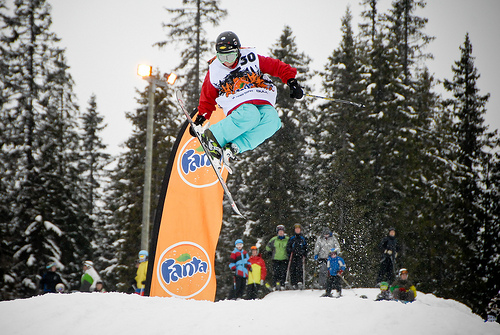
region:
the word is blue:
[164, 254, 207, 284]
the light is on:
[131, 56, 157, 81]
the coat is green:
[273, 237, 283, 255]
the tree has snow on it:
[32, 189, 67, 239]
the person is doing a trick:
[206, 40, 263, 183]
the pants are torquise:
[236, 115, 255, 133]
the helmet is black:
[209, 36, 250, 54]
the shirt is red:
[264, 57, 288, 73]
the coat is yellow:
[135, 260, 147, 282]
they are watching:
[226, 215, 357, 284]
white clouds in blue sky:
[62, 10, 111, 44]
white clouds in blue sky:
[89, 19, 144, 88]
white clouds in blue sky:
[232, 7, 288, 34]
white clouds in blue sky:
[446, 10, 487, 26]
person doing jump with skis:
[172, 31, 313, 187]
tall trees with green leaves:
[11, 20, 67, 180]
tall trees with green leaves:
[53, 90, 105, 235]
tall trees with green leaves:
[176, 7, 211, 48]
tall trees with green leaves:
[337, 30, 388, 210]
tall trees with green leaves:
[431, 38, 491, 239]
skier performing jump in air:
[176, 30, 363, 217]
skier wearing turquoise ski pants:
[205, 102, 283, 154]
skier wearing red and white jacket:
[196, 45, 297, 120]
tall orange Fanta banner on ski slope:
[146, 105, 229, 301]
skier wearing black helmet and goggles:
[215, 30, 241, 65]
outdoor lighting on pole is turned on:
[137, 63, 177, 293]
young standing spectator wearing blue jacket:
[323, 248, 348, 296]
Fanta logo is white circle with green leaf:
[157, 240, 212, 295]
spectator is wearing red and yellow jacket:
[244, 253, 267, 285]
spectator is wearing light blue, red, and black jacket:
[227, 246, 249, 275]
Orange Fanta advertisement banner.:
[154, 109, 227, 301]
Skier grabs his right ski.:
[168, 11, 365, 228]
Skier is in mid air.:
[176, 28, 353, 223]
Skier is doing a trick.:
[166, 23, 346, 213]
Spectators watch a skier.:
[225, 218, 417, 310]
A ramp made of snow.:
[2, 287, 477, 332]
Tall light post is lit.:
[128, 58, 174, 288]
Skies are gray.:
[13, 0, 498, 117]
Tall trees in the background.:
[5, 0, 491, 289]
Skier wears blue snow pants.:
[200, 93, 295, 152]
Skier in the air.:
[141, 27, 397, 242]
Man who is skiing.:
[161, 4, 326, 206]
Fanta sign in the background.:
[79, 83, 260, 318]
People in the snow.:
[215, 203, 456, 322]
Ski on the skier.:
[148, 69, 290, 276]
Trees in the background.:
[2, 5, 179, 317]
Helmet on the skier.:
[159, 23, 296, 75]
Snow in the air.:
[291, 201, 478, 303]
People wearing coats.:
[211, 215, 393, 285]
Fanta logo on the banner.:
[101, 204, 213, 294]